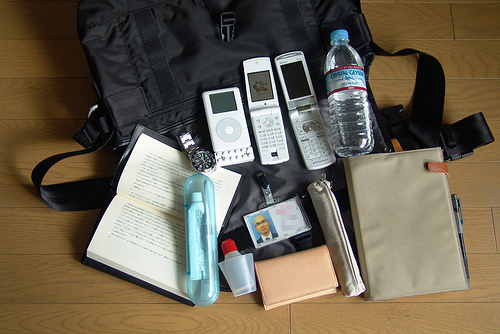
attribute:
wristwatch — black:
[144, 117, 207, 174]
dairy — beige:
[351, 135, 471, 317]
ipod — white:
[198, 94, 260, 184]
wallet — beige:
[252, 243, 342, 311]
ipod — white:
[201, 84, 253, 149]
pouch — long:
[307, 179, 366, 296]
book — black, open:
[78, 119, 248, 306]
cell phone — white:
[276, 50, 334, 169]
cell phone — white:
[242, 55, 289, 165]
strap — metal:
[175, 132, 198, 151]